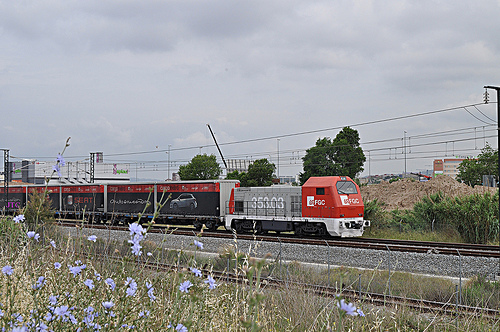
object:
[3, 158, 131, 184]
buildings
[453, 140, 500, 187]
trees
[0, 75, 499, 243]
background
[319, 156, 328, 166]
leaves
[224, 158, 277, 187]
trees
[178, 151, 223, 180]
trees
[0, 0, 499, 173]
clouds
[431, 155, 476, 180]
building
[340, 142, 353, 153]
leaves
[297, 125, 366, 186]
trees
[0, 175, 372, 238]
train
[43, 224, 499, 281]
rocks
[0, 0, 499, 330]
countryside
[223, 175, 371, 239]
locomotive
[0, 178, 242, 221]
boxcars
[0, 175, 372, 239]
freight train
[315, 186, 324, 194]
window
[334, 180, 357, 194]
window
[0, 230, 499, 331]
grass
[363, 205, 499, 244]
grass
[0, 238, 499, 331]
tracks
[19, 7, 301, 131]
sky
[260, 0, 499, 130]
sky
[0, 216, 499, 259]
tracks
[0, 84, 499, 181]
power lines